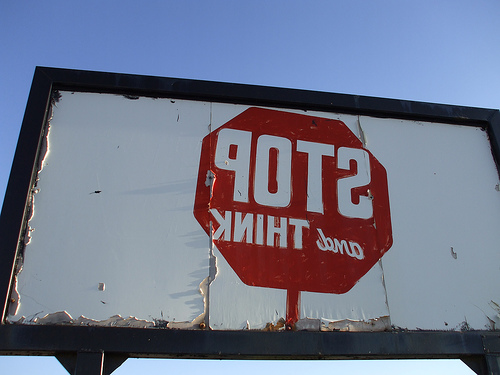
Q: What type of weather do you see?
A: It is clear.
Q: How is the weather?
A: It is clear.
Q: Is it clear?
A: Yes, it is clear.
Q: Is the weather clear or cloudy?
A: It is clear.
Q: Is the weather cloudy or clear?
A: It is clear.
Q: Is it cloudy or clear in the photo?
A: It is clear.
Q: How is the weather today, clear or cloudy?
A: It is clear.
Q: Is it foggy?
A: No, it is clear.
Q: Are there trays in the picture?
A: No, there are no trays.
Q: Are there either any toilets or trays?
A: No, there are no trays or toilets.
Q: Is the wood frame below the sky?
A: Yes, the frame is below the sky.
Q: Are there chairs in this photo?
A: No, there are no chairs.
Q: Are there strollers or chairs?
A: No, there are no chairs or strollers.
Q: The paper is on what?
A: The paper is on the frame.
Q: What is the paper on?
A: The paper is on the frame.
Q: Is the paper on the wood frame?
A: Yes, the paper is on the frame.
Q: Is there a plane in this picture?
A: No, there are no airplanes.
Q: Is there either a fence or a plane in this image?
A: No, there are no airplanes or fences.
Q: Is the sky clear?
A: Yes, the sky is clear.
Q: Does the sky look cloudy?
A: No, the sky is clear.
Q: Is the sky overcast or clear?
A: The sky is clear.